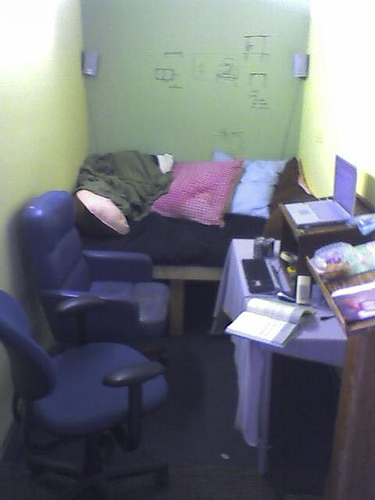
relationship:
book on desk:
[224, 294, 320, 353] [230, 230, 352, 346]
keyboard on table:
[240, 255, 276, 297] [209, 235, 349, 475]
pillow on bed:
[152, 159, 244, 227] [73, 151, 311, 262]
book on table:
[219, 289, 319, 352] [206, 234, 352, 475]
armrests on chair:
[59, 297, 165, 384] [1, 286, 175, 496]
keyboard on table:
[241, 257, 292, 297] [214, 236, 369, 491]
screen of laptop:
[332, 155, 355, 214] [284, 155, 357, 228]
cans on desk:
[248, 235, 279, 258] [210, 238, 347, 473]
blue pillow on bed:
[209, 152, 285, 218] [76, 154, 311, 282]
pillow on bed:
[150, 158, 247, 230] [76, 154, 311, 282]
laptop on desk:
[275, 151, 367, 240] [276, 185, 368, 338]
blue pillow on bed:
[228, 155, 289, 221] [75, 165, 309, 334]